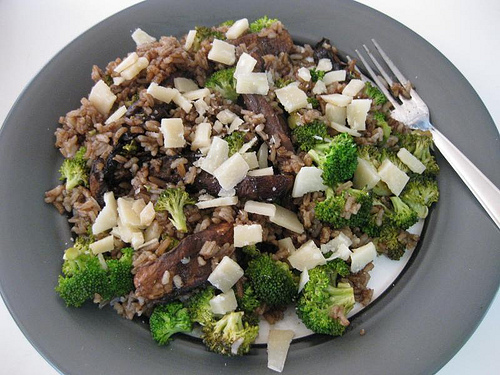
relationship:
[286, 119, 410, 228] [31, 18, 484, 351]
broccoli on plate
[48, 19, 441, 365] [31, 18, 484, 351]
dinner on plate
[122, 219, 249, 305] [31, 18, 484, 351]
meat on plate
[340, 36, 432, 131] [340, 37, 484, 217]
prongs on forks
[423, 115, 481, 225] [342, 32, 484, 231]
handle on fork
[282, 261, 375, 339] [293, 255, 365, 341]
piece of broccoli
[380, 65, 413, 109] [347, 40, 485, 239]
food on fork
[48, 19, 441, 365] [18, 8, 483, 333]
dinner on plate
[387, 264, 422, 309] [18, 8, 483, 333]
accent on plate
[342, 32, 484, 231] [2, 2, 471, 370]
fork on side of plate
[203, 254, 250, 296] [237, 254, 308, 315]
cheese flake on top of broccoli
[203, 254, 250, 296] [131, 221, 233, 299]
cheese flake on top of meat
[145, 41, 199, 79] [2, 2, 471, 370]
rice on plate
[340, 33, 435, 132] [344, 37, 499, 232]
prongs on fork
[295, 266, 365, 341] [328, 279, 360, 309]
broccoli has stalk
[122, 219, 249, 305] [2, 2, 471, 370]
meat on plate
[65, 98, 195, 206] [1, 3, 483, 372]
rice on table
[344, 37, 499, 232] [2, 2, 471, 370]
fork on plate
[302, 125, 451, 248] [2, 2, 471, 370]
broccoli on plate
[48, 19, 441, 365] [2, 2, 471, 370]
dinner on top of plate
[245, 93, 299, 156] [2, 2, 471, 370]
beef on plate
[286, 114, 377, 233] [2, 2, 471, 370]
broccoli on plate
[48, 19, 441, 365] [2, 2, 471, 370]
dinner on plate